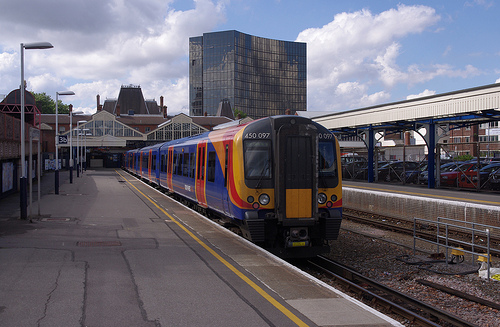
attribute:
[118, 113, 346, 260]
train — red, blue, yellow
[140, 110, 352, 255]
people — blue, passenger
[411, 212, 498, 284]
fence — metal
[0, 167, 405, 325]
platform — train boarding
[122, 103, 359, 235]
train — blue, passenger, red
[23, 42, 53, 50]
platform light — overhead